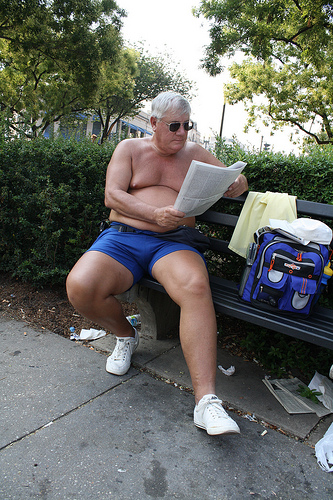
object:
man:
[65, 90, 249, 437]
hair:
[149, 89, 189, 117]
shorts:
[85, 220, 207, 295]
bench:
[136, 186, 332, 350]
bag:
[239, 219, 328, 318]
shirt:
[226, 189, 298, 259]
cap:
[267, 215, 331, 247]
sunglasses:
[154, 117, 195, 133]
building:
[9, 87, 209, 145]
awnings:
[42, 111, 152, 143]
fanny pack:
[102, 220, 211, 250]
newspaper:
[171, 158, 249, 219]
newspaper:
[261, 371, 332, 419]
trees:
[193, 0, 333, 152]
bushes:
[1, 131, 332, 370]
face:
[156, 113, 188, 150]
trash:
[217, 359, 239, 380]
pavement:
[0, 279, 332, 498]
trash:
[63, 322, 106, 344]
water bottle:
[313, 258, 333, 308]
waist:
[92, 216, 212, 251]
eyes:
[168, 122, 180, 131]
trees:
[88, 38, 199, 151]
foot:
[191, 392, 241, 437]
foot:
[103, 327, 142, 379]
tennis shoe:
[191, 393, 238, 435]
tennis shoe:
[102, 332, 142, 379]